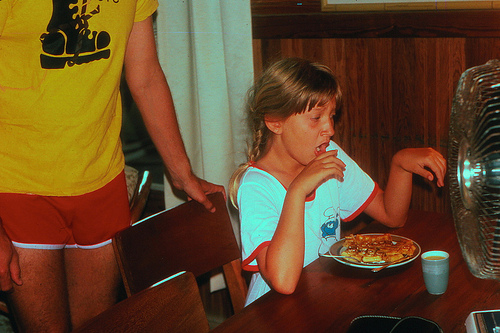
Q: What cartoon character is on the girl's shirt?
A: Smurf.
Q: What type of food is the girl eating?
A: Breakfast.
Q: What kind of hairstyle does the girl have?
A: Braid.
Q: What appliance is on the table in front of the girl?
A: Fan.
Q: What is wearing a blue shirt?
A: The little girl.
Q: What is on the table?
A: The metal fan.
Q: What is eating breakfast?
A: The young girl.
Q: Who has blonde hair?
A: The girl.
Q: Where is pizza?
A: On a plate.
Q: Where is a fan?
A: On the table.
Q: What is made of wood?
A: Table.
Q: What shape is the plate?
A: Round.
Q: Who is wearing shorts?
A: Man standing.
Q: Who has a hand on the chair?
A: The man.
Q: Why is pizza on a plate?
A: To be eaten.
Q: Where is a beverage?
A: In a cup.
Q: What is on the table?
A: Electric fan.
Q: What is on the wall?
A: Siding wood.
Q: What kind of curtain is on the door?
A: Heavy white.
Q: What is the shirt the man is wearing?
A: Yellow.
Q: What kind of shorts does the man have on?
A: Biking shorts.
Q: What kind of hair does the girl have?
A: Long blonde.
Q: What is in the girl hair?
A: Braids.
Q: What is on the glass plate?
A: Waffle.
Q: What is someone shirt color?
A: Red and white.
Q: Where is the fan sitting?
A: Table.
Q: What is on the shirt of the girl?
A: Smurf.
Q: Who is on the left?
A: Boy.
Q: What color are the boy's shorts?
A: Red.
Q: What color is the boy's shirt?
A: Yellow.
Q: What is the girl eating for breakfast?
A: Pancakes.